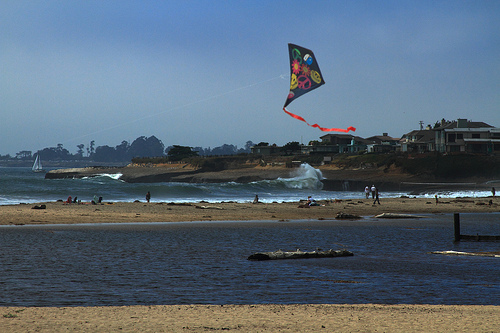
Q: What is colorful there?
A: Kite.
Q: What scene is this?
A: Beach.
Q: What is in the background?
A: Houses.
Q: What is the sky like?
A: Clear.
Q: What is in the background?
A: Patch of blue sky.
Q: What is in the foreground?
A: Sand.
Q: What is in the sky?
A: Kite.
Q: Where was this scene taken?
A: Beach.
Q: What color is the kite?
A: Black with colorful design and red tail.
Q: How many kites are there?
A: 1.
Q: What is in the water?
A: A tree log.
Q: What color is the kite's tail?
A: Red.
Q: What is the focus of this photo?
A: Flying kite at beach.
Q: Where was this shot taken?
A: Beach.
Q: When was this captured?
A: Daytime.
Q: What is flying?
A: Kite.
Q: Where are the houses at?
A: Background.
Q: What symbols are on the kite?
A: Peace, smiley, flowers.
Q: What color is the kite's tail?
A: Red.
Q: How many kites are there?
A: 1.